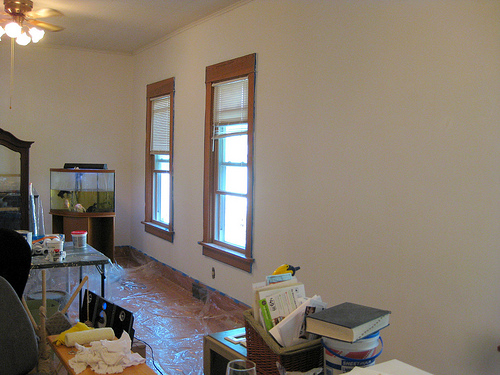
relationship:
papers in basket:
[248, 270, 328, 348] [241, 305, 324, 373]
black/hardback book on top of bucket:
[305, 302, 392, 344] [321, 330, 384, 372]